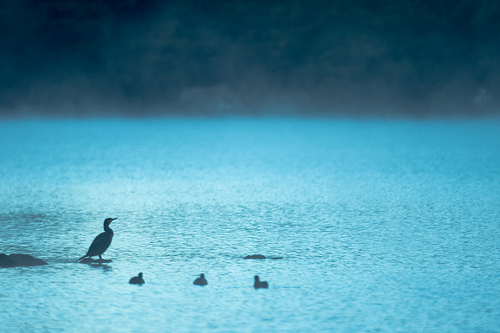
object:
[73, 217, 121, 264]
duck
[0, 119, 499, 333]
water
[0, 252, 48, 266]
rock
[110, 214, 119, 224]
beak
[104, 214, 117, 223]
head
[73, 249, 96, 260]
tail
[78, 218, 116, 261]
ducks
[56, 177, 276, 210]
reflection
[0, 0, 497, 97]
trees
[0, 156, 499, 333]
ripples